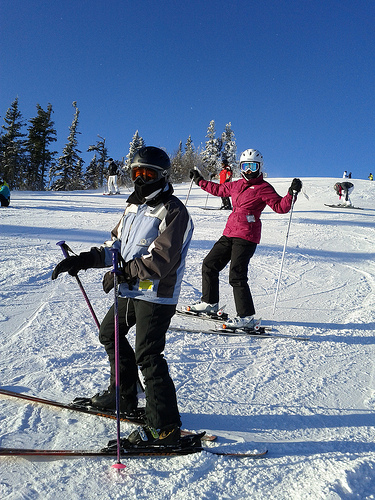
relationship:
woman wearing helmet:
[190, 144, 302, 327] [237, 147, 264, 180]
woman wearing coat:
[190, 144, 302, 328] [204, 175, 287, 240]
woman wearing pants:
[190, 144, 302, 328] [199, 233, 256, 313]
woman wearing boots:
[190, 144, 302, 328] [199, 262, 274, 335]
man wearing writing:
[51, 146, 194, 446] [4, 447, 196, 459]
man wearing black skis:
[51, 146, 194, 446] [170, 300, 280, 340]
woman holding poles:
[190, 144, 302, 327] [184, 158, 299, 283]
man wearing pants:
[47, 141, 195, 450] [87, 287, 207, 444]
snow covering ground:
[0, 176, 375, 500] [274, 89, 304, 118]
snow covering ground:
[0, 176, 375, 500] [294, 222, 346, 404]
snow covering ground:
[0, 176, 375, 500] [0, 172, 372, 497]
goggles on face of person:
[239, 159, 260, 174] [175, 132, 315, 340]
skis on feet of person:
[161, 287, 283, 346] [175, 132, 315, 340]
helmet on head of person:
[228, 139, 267, 166] [175, 132, 315, 340]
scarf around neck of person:
[332, 180, 346, 201] [324, 180, 361, 210]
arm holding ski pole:
[190, 164, 237, 202] [176, 167, 199, 204]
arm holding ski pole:
[257, 178, 289, 212] [267, 183, 293, 311]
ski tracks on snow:
[253, 209, 372, 344] [0, 176, 375, 500]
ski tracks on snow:
[170, 340, 372, 419] [0, 176, 375, 500]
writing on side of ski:
[4, 447, 196, 459] [0, 434, 216, 474]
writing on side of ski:
[0, 390, 171, 432] [3, 371, 203, 435]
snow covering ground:
[281, 232, 357, 363] [0, 172, 372, 497]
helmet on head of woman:
[240, 148, 264, 179] [190, 144, 302, 327]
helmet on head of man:
[126, 143, 173, 180] [47, 141, 195, 450]